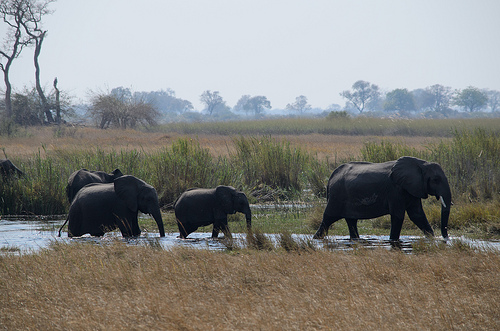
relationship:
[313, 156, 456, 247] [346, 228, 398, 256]
elephant walking in water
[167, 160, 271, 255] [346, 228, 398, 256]
elephant walking in water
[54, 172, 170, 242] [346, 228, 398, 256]
elephant walking in water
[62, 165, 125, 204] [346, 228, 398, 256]
elephant walking in water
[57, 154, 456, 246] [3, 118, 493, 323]
elephants walking in marsh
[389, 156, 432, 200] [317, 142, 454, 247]
ear on elephant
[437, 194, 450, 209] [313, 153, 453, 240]
tusk on elephant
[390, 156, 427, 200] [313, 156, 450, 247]
ear on elephant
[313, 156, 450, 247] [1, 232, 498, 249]
elephant in water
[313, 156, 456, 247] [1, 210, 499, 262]
elephant in water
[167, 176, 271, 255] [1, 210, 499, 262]
elephant in water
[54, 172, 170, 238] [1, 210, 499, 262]
elephant in water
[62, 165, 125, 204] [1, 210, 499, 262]
elephant in water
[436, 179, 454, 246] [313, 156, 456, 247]
trunk of elephant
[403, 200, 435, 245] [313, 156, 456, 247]
leg of elephant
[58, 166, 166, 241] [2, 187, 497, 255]
elephants in marsh